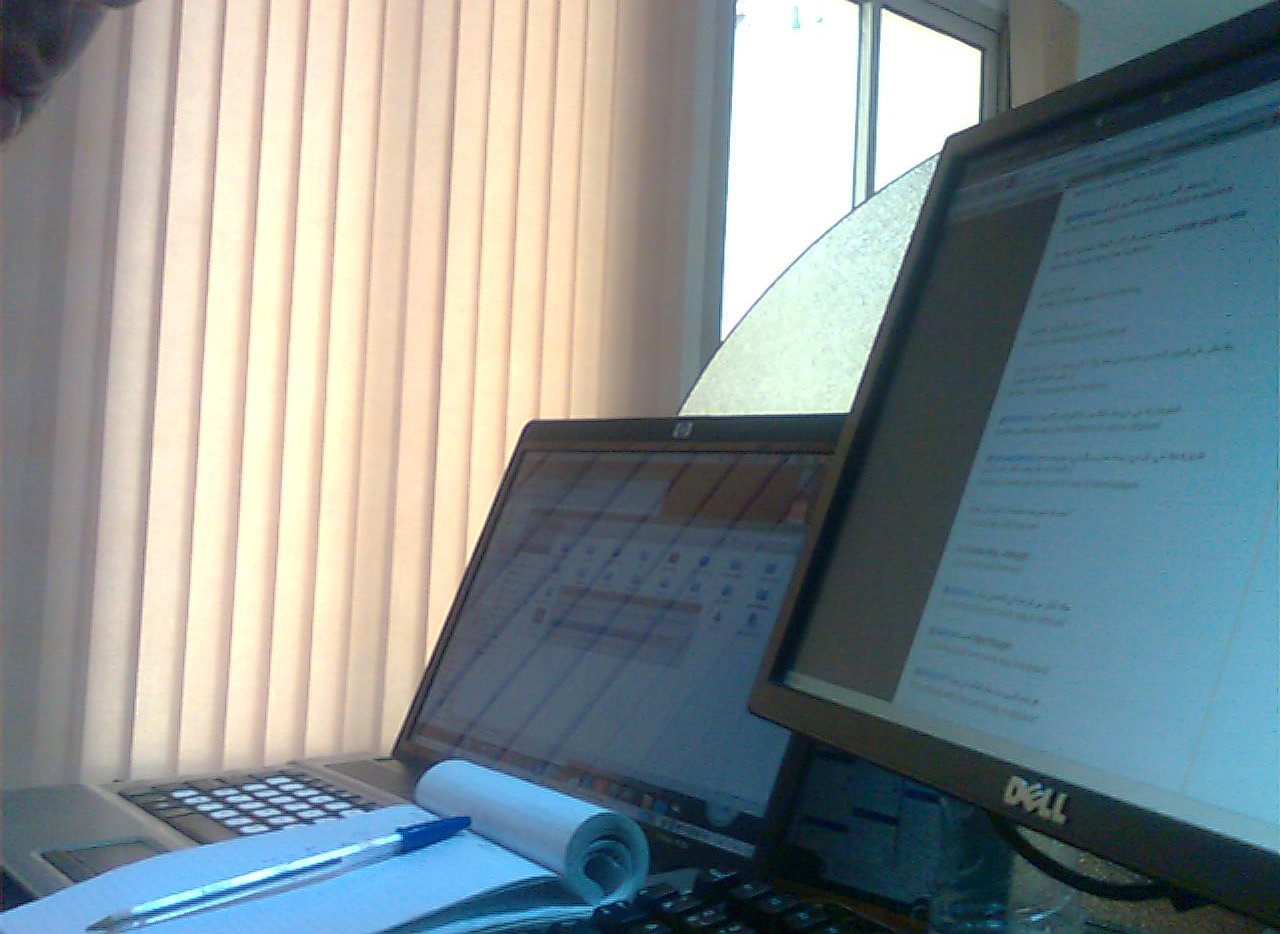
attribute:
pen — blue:
[93, 805, 504, 930]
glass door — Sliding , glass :
[713, 0, 992, 360]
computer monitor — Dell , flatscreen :
[762, 16, 1276, 921]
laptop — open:
[1, 393, 871, 916]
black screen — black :
[759, 7, 1268, 921]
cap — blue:
[394, 802, 477, 853]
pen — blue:
[82, 809, 477, 927]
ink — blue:
[129, 847, 340, 923]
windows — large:
[704, 6, 994, 455]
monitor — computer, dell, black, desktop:
[717, 9, 1275, 928]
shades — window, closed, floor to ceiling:
[5, 2, 745, 825]